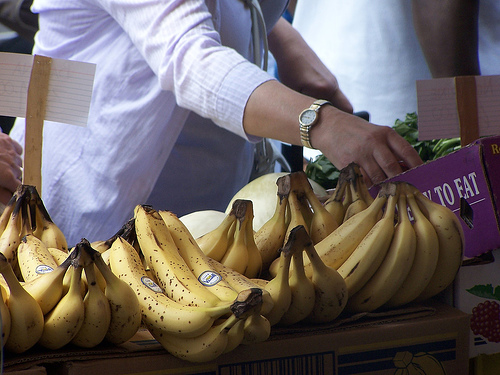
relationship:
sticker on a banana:
[197, 265, 222, 290] [160, 206, 272, 338]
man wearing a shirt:
[7, 0, 426, 247] [25, 0, 315, 287]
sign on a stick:
[0, 52, 97, 128] [20, 53, 52, 196]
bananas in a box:
[105, 196, 275, 369] [0, 294, 471, 374]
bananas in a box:
[5, 154, 468, 370] [0, 294, 471, 374]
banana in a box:
[127, 197, 266, 310] [0, 294, 471, 374]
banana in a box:
[104, 230, 234, 339] [0, 294, 471, 374]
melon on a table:
[176, 209, 231, 237] [15, 315, 454, 375]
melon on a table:
[223, 173, 325, 225] [15, 315, 454, 375]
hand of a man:
[325, 114, 422, 183] [7, 0, 426, 247]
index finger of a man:
[387, 130, 421, 169] [7, 0, 426, 247]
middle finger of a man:
[373, 143, 403, 180] [7, 0, 426, 247]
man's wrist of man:
[294, 97, 340, 149] [7, 0, 426, 247]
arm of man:
[102, 1, 422, 193] [7, 0, 426, 247]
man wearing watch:
[7, 0, 426, 247] [298, 97, 330, 148]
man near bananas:
[7, 0, 426, 247] [266, 179, 464, 314]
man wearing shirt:
[7, 0, 426, 247] [8, 0, 291, 249]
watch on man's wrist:
[286, 89, 333, 136] [294, 97, 334, 154]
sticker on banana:
[197, 270, 222, 288] [163, 211, 253, 321]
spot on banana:
[147, 302, 153, 314] [103, 235, 213, 336]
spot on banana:
[175, 323, 182, 335] [103, 235, 213, 336]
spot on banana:
[167, 276, 173, 284] [103, 235, 213, 336]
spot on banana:
[152, 227, 163, 254] [103, 235, 213, 336]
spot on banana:
[154, 258, 159, 263] [103, 235, 213, 336]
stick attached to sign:
[15, 49, 51, 191] [0, 55, 95, 126]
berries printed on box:
[464, 295, 499, 349] [443, 237, 499, 352]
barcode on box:
[219, 354, 334, 373] [54, 320, 469, 371]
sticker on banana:
[197, 270, 222, 288] [153, 209, 276, 345]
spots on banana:
[137, 259, 187, 309] [114, 205, 267, 358]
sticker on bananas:
[197, 270, 222, 288] [105, 194, 285, 356]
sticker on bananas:
[138, 265, 165, 295] [105, 194, 285, 356]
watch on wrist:
[298, 99, 331, 149] [285, 94, 365, 154]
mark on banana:
[147, 297, 157, 315] [145, 315, 237, 363]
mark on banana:
[153, 305, 164, 329] [145, 315, 237, 363]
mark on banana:
[183, 313, 201, 331] [145, 315, 237, 363]